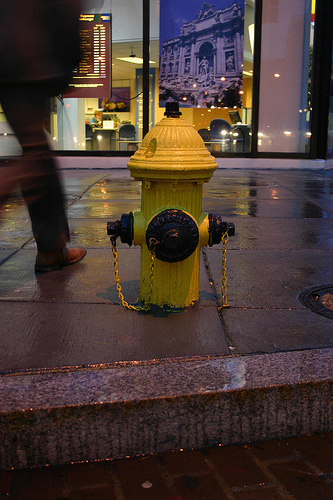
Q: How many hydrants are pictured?
A: One.